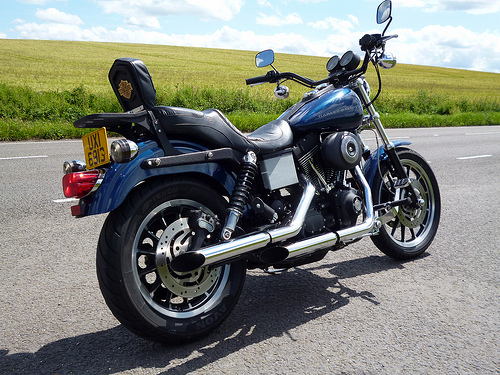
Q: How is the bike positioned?
A: Parked.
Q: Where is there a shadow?
A: Below bike.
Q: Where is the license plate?
A: Back of bike.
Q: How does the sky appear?
A: Cloudy.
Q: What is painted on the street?
A: White dashes.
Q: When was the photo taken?
A: In the daytime.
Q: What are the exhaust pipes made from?
A: Chrome.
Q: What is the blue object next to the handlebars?
A: Gas tank.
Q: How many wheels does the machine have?
A: Two.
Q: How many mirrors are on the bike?
A: Two.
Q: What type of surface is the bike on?
A: Gravel.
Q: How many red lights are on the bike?
A: One.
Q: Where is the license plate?
A: Rear.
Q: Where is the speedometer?
A: On the handlebars.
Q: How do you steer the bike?
A: With handlebars.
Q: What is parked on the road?
A: A motorcycle.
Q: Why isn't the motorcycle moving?
A: It's parked.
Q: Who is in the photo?
A: Nobody.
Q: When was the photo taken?
A: Daytime.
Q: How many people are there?
A: None.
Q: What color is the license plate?
A: Yellow.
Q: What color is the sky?
A: Blue.